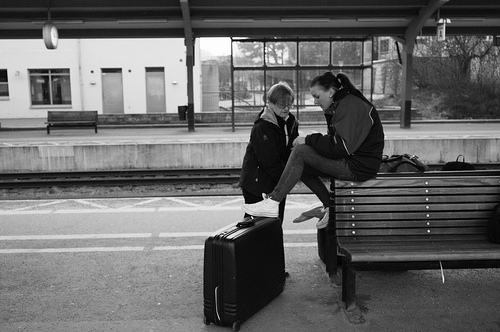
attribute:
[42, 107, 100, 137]
bench — empty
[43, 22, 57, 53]
clock — analog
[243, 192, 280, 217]
sneaker — white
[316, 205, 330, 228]
sneaker — white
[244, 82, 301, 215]
woman — old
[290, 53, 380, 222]
woman — young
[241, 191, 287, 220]
tennis shoe — white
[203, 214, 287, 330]
suitcase — hard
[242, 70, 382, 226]
woman — old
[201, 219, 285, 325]
suitcase — large, black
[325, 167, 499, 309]
bench — wooden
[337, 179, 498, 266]
bench — wood